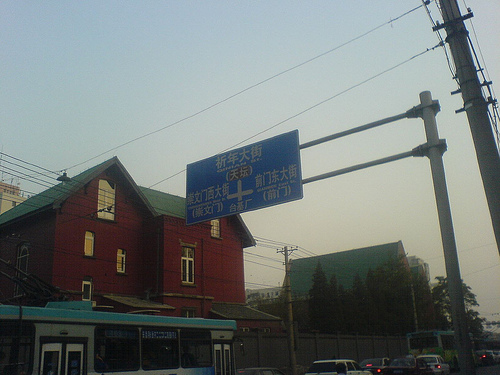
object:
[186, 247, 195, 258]
window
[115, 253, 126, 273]
window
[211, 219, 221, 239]
window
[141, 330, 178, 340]
sign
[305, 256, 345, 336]
trees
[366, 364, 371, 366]
light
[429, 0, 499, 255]
powerline pole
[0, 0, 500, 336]
sky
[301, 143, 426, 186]
sign pole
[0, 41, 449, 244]
power line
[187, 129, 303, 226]
blue sign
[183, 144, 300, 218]
chinese writing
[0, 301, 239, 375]
bus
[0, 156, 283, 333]
building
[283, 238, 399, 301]
roof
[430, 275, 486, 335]
trees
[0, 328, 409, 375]
fence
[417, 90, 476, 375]
post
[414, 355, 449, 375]
hatchback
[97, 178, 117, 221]
window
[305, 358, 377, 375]
car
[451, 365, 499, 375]
road